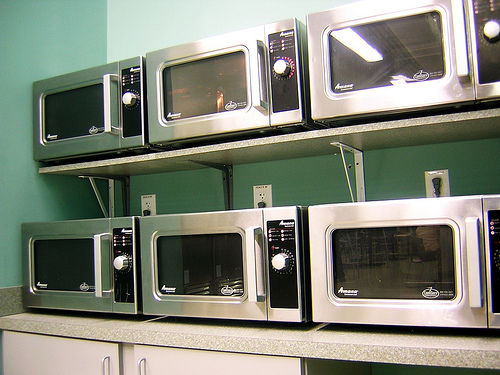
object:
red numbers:
[273, 57, 296, 80]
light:
[160, 27, 265, 140]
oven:
[29, 0, 500, 166]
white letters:
[166, 110, 182, 119]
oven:
[302, 191, 500, 337]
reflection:
[332, 223, 457, 294]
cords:
[137, 175, 449, 217]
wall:
[0, 0, 500, 375]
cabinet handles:
[97, 354, 145, 374]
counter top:
[0, 310, 500, 375]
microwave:
[12, 191, 500, 334]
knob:
[271, 252, 290, 271]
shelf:
[37, 109, 499, 179]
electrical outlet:
[252, 184, 273, 208]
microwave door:
[139, 208, 268, 326]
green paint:
[0, 170, 51, 286]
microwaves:
[29, 0, 499, 168]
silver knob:
[272, 252, 292, 273]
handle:
[94, 356, 120, 375]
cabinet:
[5, 327, 324, 371]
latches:
[327, 139, 367, 203]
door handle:
[250, 40, 267, 113]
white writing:
[338, 287, 358, 298]